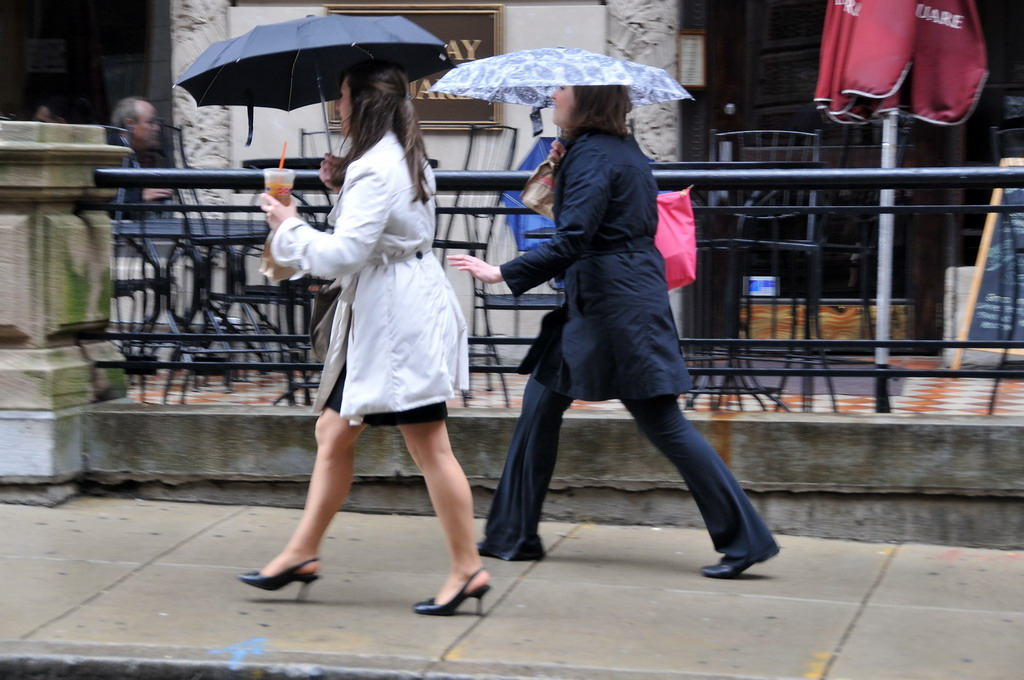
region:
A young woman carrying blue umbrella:
[239, 64, 489, 614]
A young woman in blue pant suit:
[478, 87, 782, 582]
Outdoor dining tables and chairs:
[101, 131, 844, 416]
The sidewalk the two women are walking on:
[0, 487, 1021, 674]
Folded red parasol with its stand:
[812, 5, 987, 416]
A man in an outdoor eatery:
[113, 93, 172, 205]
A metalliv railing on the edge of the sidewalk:
[114, 166, 1016, 417]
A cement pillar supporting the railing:
[0, 122, 134, 505]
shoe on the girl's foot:
[369, 508, 528, 655]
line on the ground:
[780, 513, 997, 662]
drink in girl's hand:
[193, 127, 329, 271]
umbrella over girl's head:
[139, 3, 460, 146]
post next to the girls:
[739, 110, 1012, 266]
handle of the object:
[288, 72, 365, 199]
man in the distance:
[65, 58, 212, 195]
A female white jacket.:
[270, 126, 479, 424]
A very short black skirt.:
[322, 374, 452, 426]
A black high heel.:
[223, 553, 326, 604]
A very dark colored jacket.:
[498, 124, 705, 403]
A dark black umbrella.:
[176, 13, 453, 116]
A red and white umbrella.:
[809, 0, 993, 418]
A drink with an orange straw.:
[261, 136, 299, 222]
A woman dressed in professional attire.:
[429, 44, 791, 582]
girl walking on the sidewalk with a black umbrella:
[174, 10, 492, 614]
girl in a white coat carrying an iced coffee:
[258, 73, 496, 614]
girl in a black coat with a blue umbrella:
[435, 47, 783, 578]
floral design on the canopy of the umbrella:
[427, 42, 693, 119]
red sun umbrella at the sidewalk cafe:
[815, 0, 992, 413]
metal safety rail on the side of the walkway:
[97, 160, 257, 405]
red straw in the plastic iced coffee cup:
[261, 139, 303, 228]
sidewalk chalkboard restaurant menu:
[950, 157, 1023, 383]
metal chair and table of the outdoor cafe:
[694, 119, 840, 418]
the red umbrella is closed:
[810, 4, 987, 422]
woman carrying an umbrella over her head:
[188, 20, 489, 613]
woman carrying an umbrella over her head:
[444, 43, 790, 572]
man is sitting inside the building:
[90, 92, 189, 190]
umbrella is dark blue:
[168, 14, 451, 185]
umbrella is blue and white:
[431, 42, 687, 180]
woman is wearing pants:
[460, 77, 778, 577]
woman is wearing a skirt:
[247, 77, 511, 616]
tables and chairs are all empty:
[68, 150, 1021, 413]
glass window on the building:
[887, 119, 948, 309]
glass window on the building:
[990, 1, 1019, 100]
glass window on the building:
[0, 1, 143, 113]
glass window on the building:
[744, 6, 818, 115]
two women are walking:
[157, 13, 802, 620]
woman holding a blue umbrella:
[159, 6, 454, 142]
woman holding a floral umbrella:
[433, 16, 683, 146]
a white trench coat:
[228, 64, 503, 445]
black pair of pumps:
[218, 549, 507, 620]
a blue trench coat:
[481, 92, 707, 407]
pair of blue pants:
[480, 376, 788, 573]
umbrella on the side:
[800, 13, 984, 390]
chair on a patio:
[692, 88, 835, 427]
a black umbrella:
[171, 15, 454, 216]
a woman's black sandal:
[409, 565, 495, 627]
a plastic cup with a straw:
[264, 136, 297, 212]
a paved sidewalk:
[0, 490, 1022, 677]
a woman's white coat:
[272, 124, 475, 420]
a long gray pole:
[873, 110, 899, 393]